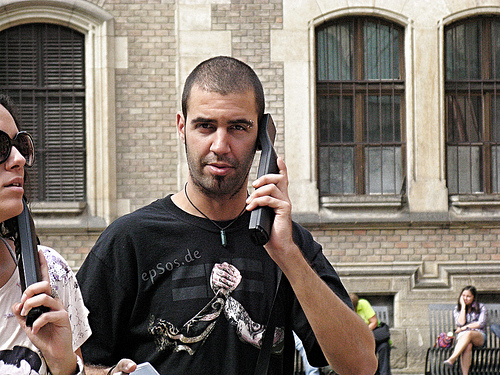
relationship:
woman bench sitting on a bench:
[440, 281, 489, 373] [426, 299, 497, 371]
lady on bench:
[436, 266, 486, 350] [419, 300, 499, 374]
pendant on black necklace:
[207, 222, 232, 253] [177, 180, 251, 231]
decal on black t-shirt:
[164, 262, 278, 346] [64, 192, 355, 375]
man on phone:
[80, 52, 384, 372] [238, 104, 288, 248]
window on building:
[15, 30, 150, 197] [21, 23, 496, 298]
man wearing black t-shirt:
[80, 52, 384, 372] [64, 192, 355, 375]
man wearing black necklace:
[80, 52, 384, 372] [184, 181, 252, 248]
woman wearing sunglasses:
[3, 92, 93, 373] [0, 127, 35, 166]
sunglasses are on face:
[0, 123, 42, 170] [0, 104, 35, 217]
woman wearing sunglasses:
[3, 92, 93, 373] [0, 123, 42, 170]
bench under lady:
[419, 300, 499, 374] [439, 282, 494, 374]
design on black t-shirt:
[145, 263, 282, 360] [64, 192, 355, 375]